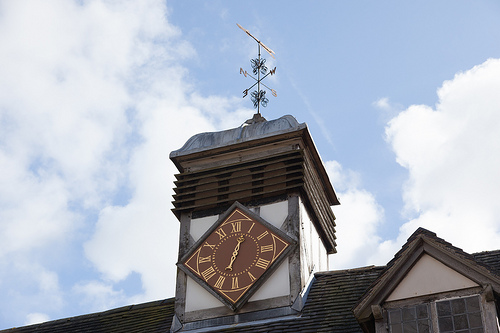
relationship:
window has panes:
[370, 282, 499, 332] [385, 292, 486, 332]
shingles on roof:
[96, 307, 174, 328] [55, 263, 480, 320]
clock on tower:
[172, 203, 296, 317] [164, 110, 344, 330]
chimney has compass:
[146, 111, 363, 312] [221, 18, 287, 108]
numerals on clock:
[218, 271, 241, 291] [172, 203, 296, 317]